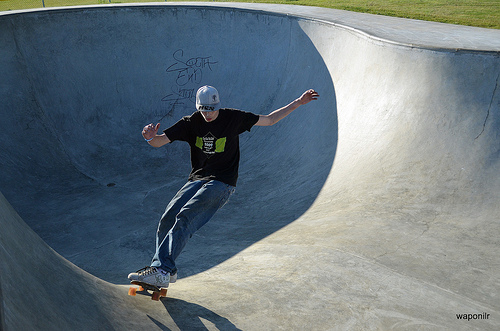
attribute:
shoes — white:
[132, 253, 180, 289]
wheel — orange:
[121, 283, 140, 301]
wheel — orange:
[135, 282, 148, 295]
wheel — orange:
[148, 287, 162, 303]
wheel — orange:
[157, 282, 174, 301]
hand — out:
[135, 116, 164, 147]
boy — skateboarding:
[145, 67, 285, 300]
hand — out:
[293, 79, 321, 108]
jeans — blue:
[145, 166, 229, 272]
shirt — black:
[171, 104, 257, 183]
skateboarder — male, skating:
[103, 50, 320, 296]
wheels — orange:
[121, 282, 160, 302]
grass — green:
[339, 0, 494, 25]